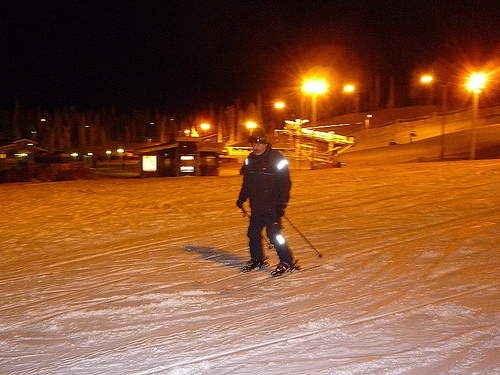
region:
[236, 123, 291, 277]
man wearing back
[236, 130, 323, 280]
man holding ski poles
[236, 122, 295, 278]
a man with three reflectors on his cloths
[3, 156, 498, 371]
ski tracks in the white snow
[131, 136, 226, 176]
a small building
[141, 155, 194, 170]
two illuminated windows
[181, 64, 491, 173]
lights on tall poles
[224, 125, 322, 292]
a man with a beard skiing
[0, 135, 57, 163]
a building with illuminated windows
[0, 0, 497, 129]
a dark night sky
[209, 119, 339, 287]
A person in the foreground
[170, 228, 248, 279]
Person is casting a shadow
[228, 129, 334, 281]
Person is skiing in the snow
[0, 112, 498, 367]
Snow is covering the ground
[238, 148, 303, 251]
Person is wearing reflective clothing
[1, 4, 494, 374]
Photo was taken at night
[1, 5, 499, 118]
The sky is black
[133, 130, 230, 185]
A small building in the background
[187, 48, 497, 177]
The lights are orange in color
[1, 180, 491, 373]
Tracks are in the snow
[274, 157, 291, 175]
A reflective light on the man's shoulder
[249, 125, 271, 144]
A black hat on the man's head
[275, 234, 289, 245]
A bright light on the man's knee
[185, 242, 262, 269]
Small black shadow of the man in the snow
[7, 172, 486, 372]
Thick white snow covers the ground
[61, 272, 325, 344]
Tracks clearly visible in the snow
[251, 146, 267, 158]
The man has a short grey beard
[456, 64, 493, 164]
A wooden pole with a bright light atop it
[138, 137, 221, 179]
A small wooden building behind the man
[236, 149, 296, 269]
The man wears a dark blue snow suit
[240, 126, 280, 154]
head of a person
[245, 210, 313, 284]
legs of a person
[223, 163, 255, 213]
arm of a person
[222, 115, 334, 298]
person wearing a black jacket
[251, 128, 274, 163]
person wearing hat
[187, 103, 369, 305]
person holding two snow sticks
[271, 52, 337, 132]
street lights on street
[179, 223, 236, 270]
shadow of a person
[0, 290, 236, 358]
a snowy field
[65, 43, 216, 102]
a dark sky with no clouds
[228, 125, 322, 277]
a man skiing down a slope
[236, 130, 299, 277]
a man wearing a dark ski suit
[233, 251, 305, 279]
a pair of ski boots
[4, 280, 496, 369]
ski prints in the snow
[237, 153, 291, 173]
reflective material on the shoulders of a jacket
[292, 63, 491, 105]
bright lights on a ski slope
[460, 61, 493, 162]
bright light on a pole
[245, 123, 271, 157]
the head of a man wearing a ski hat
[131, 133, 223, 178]
a small wooden shed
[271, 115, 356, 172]
a snow spreading machine